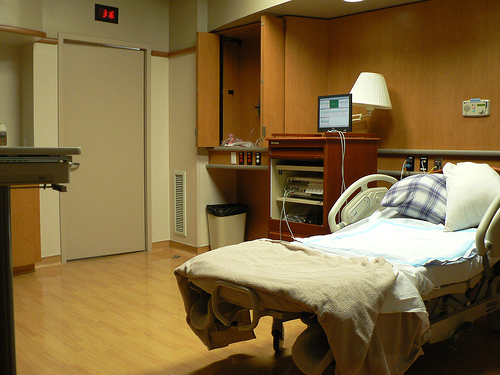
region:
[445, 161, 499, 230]
a white pillow next to a plaid pillow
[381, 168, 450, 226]
a plaid pillow on a hospital bed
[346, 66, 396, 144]
a lamp on a dresser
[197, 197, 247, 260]
a trash can under a shelf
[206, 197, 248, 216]
a black bag in a trash can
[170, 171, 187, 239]
a white vent in a wall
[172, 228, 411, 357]
a blanket folded at the end of a hospital bed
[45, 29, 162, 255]
a door in a room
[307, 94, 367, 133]
a monitor on top of a dresser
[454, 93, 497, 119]
a control box above a hospital bed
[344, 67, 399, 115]
a white lamp shade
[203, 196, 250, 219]
a black trash bag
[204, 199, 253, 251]
a gray trash can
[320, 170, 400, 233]
a white arm of the bed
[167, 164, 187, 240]
a vent on the wall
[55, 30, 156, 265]
a gray elevator door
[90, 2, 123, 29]
a number over the door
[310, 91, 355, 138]
a black computer screen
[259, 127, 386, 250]
a brown dresser by the bed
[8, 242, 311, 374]
a brown wood floor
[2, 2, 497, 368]
a hospitol or other health care facility room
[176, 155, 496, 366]
a hospitol-style bed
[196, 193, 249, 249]
trash bin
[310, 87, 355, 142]
monitor displaying information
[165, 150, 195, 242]
a vent in the wall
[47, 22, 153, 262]
a large beige metal door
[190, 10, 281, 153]
open cabinet doors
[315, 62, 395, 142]
a lamp with a white shade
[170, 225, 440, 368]
blanket across foot of bed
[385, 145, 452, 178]
cords plugged into outlets on wall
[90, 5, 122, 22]
digital wall clock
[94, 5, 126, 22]
digital wall clock with red text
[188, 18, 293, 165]
open tan wooden cabinet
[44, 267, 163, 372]
tan wooden floor boards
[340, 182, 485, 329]
empty white hospital bed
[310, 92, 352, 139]
small computer monitor on shelf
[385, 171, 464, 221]
blue and white pillow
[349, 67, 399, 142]
tilted white lamp on shelf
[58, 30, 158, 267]
tan door slightly ajar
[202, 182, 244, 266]
black and tan trashcan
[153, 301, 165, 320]
the floor is wooden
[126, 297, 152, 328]
the floor is wooden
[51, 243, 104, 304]
the floor is wooden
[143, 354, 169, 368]
the floor is wooden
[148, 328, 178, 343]
the floor is wooden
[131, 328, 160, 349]
the floor is wooden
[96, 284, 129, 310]
the floor is wooden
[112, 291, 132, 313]
the floor is wooden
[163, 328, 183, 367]
the floor is wooden